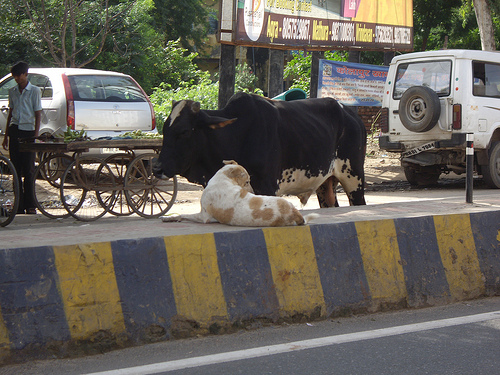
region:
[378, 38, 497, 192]
a whiten truck on a road,.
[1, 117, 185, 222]
A group of bikes.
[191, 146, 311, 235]
a dog on a sidewalk.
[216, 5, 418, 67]
A sign in a parking.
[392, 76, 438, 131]
A tire on the back of a jeep.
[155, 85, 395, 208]
a cow on a sidewalk.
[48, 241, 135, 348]
A yellow stripe on a sidewalk.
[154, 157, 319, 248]
tan and white dog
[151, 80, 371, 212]
big black and white cow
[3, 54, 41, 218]
man in blue shirt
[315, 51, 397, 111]
blue and red sign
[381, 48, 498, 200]
White truck with tire on back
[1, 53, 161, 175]
silver colored car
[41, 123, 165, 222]
wagons with vegetables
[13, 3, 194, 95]
there are tall trees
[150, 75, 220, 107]
there are bushes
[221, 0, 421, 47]
there is a billboard advertisement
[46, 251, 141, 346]
yellow stripe on wall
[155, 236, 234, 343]
yellow stripe on wall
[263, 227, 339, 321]
yellow stripe on wall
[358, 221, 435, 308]
yellow stripe on wall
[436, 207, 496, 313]
yellow stripe on wall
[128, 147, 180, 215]
wooden wheel on cart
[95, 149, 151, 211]
wooden wheel on cart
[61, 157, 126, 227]
wooden wheel on cart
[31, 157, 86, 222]
wooden wheel on cart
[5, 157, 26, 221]
wooden wheel on cart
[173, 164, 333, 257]
this is a dog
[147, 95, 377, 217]
this is a cow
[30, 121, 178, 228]
this is a bike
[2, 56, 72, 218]
this is a man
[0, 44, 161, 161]
this is a car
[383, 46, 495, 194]
this is a car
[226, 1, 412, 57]
this is a sign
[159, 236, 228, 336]
this is a yellow line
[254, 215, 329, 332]
this is a yellow line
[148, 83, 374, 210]
large black cow standing on side of street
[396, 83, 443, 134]
black tire on back of vehicle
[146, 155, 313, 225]
tan and white dog lying next to black cow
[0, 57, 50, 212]
man in blue shirt standing in front of wooden table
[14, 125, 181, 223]
wooden table with large wheels beneath it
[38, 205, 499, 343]
yellow wide lines painted on raised cement surface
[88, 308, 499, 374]
white line painted on asphalt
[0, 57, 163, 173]
silver car parked behind man in blue shirt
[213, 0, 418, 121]
raised advertising billboard on side of street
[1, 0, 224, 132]
trees and brush next to silver car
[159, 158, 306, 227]
dog laying on the ground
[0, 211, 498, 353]
black and yellow stripes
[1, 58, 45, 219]
skinny man with hand in his pocket